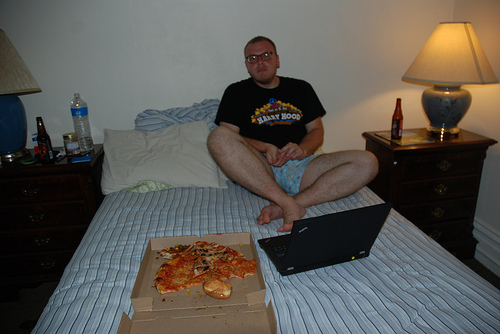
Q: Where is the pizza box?
A: On the bed.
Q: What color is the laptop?
A: Black.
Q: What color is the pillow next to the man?
A: White.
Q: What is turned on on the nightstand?
A: The lamp.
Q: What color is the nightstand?
A: Brown.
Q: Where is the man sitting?
A: On the bed.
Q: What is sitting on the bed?
A: A black laptop.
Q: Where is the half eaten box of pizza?
A: Sitting on the bed.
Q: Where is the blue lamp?
A: Sitting on the nightstand.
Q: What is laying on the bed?
A: A pillow with a white pillow case.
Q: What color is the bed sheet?
A: Blue and gray striped.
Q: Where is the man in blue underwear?
A: Sitting on the bed.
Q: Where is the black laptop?
A: On the bed by the man's feet.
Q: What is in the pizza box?
A: Half a pizza.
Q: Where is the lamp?
A: On the nightstand.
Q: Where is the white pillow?
A: On the bed.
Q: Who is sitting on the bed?
A: A man.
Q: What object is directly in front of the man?
A: A laptop.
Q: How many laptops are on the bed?
A: One.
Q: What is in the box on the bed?
A: Pizza.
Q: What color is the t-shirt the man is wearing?
A: Black.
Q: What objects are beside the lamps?
A: Bottles.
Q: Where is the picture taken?
A: Bedroom.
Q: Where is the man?
A: On a bed.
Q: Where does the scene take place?
A: In a bedroom.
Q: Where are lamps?
A: On side tables.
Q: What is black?
A: Man's shirt.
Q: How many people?
A: One.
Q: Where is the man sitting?
A: On the bed.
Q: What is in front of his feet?
A: Laptop.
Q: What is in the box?
A: Pizza.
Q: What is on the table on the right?
A: Beer and lamp.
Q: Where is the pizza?
A: On the bed.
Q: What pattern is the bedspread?
A: Striped.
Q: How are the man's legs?
A: Crossed.